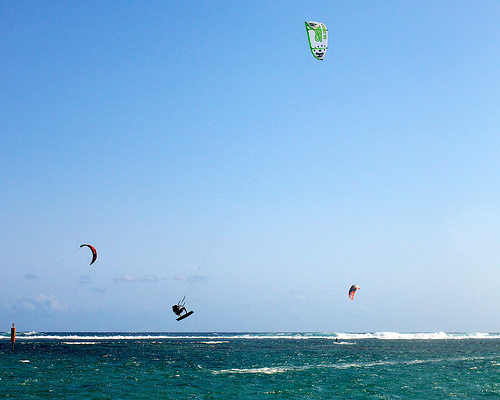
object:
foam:
[0, 330, 499, 341]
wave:
[64, 338, 229, 347]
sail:
[304, 21, 329, 62]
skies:
[0, 0, 499, 333]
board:
[174, 310, 194, 322]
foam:
[211, 352, 499, 380]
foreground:
[0, 342, 499, 399]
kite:
[346, 283, 359, 301]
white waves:
[0, 329, 498, 345]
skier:
[170, 303, 188, 317]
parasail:
[78, 243, 98, 266]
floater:
[0, 323, 23, 348]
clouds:
[0, 292, 74, 322]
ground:
[383, 84, 422, 112]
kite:
[78, 244, 97, 266]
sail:
[78, 242, 96, 265]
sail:
[345, 282, 360, 300]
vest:
[172, 308, 180, 317]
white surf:
[212, 356, 499, 377]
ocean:
[0, 329, 499, 399]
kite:
[303, 20, 327, 61]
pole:
[11, 322, 18, 344]